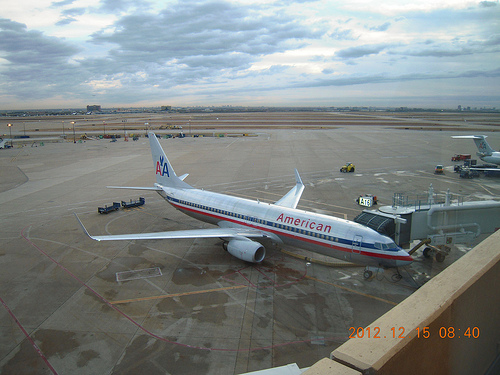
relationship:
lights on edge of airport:
[2, 116, 84, 146] [0, 112, 500, 375]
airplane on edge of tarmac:
[75, 124, 418, 266] [0, 110, 497, 372]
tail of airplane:
[107, 132, 195, 191] [84, 132, 426, 276]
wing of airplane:
[71, 210, 279, 242] [75, 124, 418, 266]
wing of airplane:
[269, 142, 331, 204] [108, 117, 444, 294]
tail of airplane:
[107, 132, 195, 191] [75, 124, 418, 266]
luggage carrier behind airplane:
[97, 196, 145, 214] [75, 124, 418, 266]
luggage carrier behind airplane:
[96, 200, 119, 215] [75, 124, 418, 266]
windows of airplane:
[157, 192, 341, 250] [75, 124, 418, 266]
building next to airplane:
[371, 177, 481, 250] [58, 109, 420, 311]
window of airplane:
[370, 237, 403, 256] [144, 134, 425, 290]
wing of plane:
[73, 211, 277, 241] [75, 130, 418, 298]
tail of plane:
[450, 127, 494, 164] [75, 130, 418, 298]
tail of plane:
[107, 127, 194, 200] [450, 130, 498, 172]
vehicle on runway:
[335, 162, 359, 172] [222, 130, 344, 162]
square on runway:
[112, 264, 163, 284] [0, 129, 498, 372]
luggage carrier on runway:
[97, 196, 145, 214] [0, 129, 498, 372]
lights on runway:
[3, 118, 79, 140] [3, 127, 393, 132]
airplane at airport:
[74, 132, 414, 278] [4, 113, 497, 287]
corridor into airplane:
[369, 197, 499, 247] [74, 132, 414, 278]